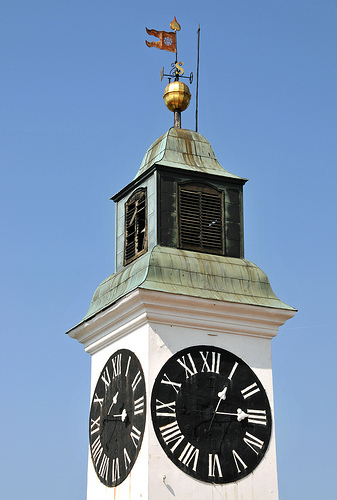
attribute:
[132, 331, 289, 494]
clock — facing, faces, white, pointing, tower, large, hand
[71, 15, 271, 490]
tower — white, clock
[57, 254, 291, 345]
roof — green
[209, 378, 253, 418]
hand — white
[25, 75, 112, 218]
sky — blue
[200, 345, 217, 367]
numeral — roman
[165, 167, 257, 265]
window — old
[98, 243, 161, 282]
rusting — some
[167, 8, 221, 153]
rod — large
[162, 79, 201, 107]
ball — golden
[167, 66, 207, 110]
orb — golden